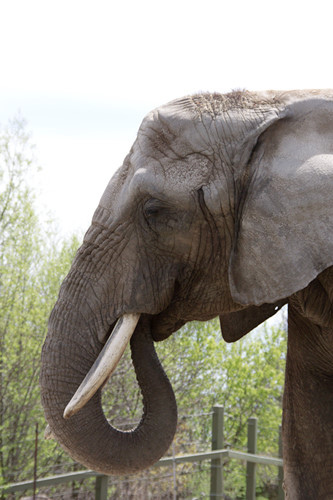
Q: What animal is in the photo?
A: Elephant.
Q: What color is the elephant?
A: Grey.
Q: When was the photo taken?
A: Daytime.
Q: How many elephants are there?
A: One.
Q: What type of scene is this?
A: Outdoor.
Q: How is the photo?
A: Clear.